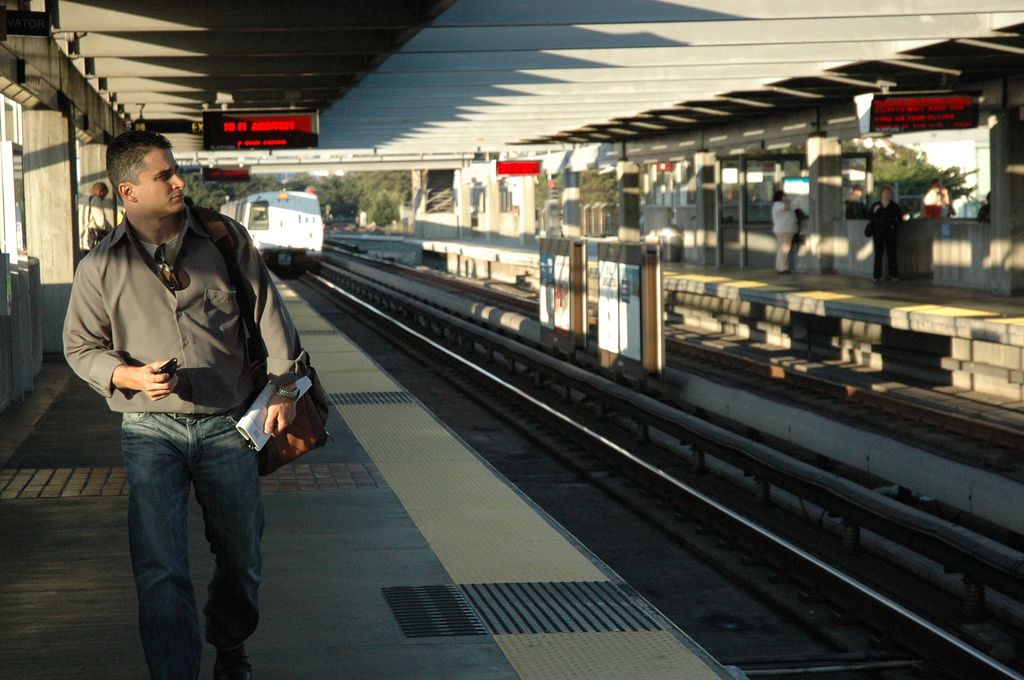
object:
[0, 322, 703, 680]
ground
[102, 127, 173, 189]
hair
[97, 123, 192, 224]
head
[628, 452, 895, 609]
rod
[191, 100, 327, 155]
sign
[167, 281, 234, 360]
wrinkle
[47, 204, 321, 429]
shirt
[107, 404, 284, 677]
blue jeans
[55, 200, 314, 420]
gray shirt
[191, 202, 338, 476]
bag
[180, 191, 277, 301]
shoulder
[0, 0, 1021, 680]
train station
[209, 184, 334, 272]
train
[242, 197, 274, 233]
window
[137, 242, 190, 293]
sunglasses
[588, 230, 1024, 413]
platform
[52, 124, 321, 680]
man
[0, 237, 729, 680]
platform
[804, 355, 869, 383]
shadow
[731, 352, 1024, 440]
tracks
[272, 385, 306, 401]
watch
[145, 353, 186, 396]
cellphone